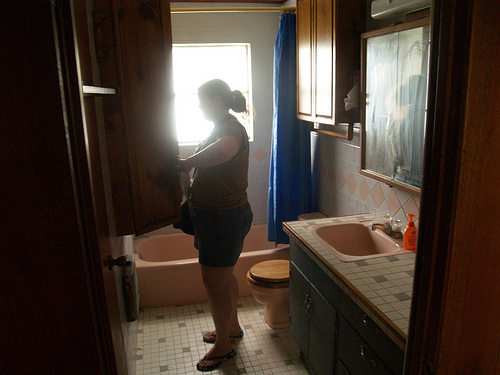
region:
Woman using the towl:
[168, 79, 256, 369]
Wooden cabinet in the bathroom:
[293, 2, 368, 141]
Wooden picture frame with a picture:
[357, 4, 440, 194]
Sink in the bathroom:
[314, 223, 399, 261]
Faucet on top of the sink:
[367, 213, 405, 244]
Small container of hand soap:
[402, 212, 420, 250]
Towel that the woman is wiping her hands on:
[72, 4, 182, 236]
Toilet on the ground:
[246, 257, 290, 334]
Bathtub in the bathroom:
[126, 225, 291, 306]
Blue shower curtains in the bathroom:
[267, 6, 322, 248]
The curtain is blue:
[271, 10, 318, 237]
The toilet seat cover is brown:
[243, 254, 299, 299]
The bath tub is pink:
[130, 222, 302, 302]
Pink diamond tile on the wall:
[324, 153, 432, 238]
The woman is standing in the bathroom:
[177, 65, 264, 367]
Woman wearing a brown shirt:
[178, 73, 258, 210]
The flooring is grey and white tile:
[140, 306, 288, 369]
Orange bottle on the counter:
[398, 199, 420, 254]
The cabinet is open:
[78, 6, 190, 222]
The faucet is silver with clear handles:
[368, 210, 405, 253]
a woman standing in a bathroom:
[163, 78, 255, 373]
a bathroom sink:
[309, 215, 396, 260]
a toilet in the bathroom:
[247, 210, 326, 325]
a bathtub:
[128, 215, 298, 306]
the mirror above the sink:
[360, 30, 435, 194]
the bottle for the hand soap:
[403, 212, 418, 251]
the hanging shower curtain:
[263, 6, 314, 243]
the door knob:
[109, 249, 130, 272]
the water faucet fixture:
[368, 213, 401, 238]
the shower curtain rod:
[167, 3, 296, 15]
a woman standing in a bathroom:
[63, 11, 448, 366]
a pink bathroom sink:
[309, 209, 405, 265]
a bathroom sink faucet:
[364, 209, 403, 239]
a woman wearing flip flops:
[173, 75, 262, 372]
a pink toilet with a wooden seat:
[248, 258, 301, 332]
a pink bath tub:
[131, 225, 309, 309]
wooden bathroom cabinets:
[294, 0, 366, 145]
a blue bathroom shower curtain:
[261, 6, 316, 242]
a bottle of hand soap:
[399, 209, 418, 256]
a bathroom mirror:
[351, 29, 437, 188]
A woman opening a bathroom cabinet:
[54, 40, 276, 363]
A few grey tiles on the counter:
[354, 247, 415, 307]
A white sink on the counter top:
[318, 220, 388, 262]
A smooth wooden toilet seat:
[246, 252, 302, 293]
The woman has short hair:
[192, 82, 243, 124]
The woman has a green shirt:
[178, 120, 257, 208]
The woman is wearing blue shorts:
[179, 194, 256, 268]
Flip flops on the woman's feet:
[192, 323, 255, 371]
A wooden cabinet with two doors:
[277, 5, 357, 128]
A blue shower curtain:
[262, 0, 319, 237]